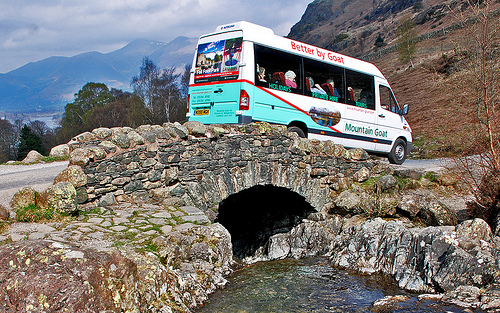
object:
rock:
[111, 176, 129, 186]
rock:
[141, 157, 156, 168]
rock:
[145, 145, 157, 155]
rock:
[352, 165, 367, 182]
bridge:
[74, 124, 402, 249]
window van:
[249, 44, 298, 99]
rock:
[95, 186, 106, 193]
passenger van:
[183, 20, 431, 161]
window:
[343, 65, 376, 112]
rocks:
[266, 130, 280, 138]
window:
[303, 60, 344, 104]